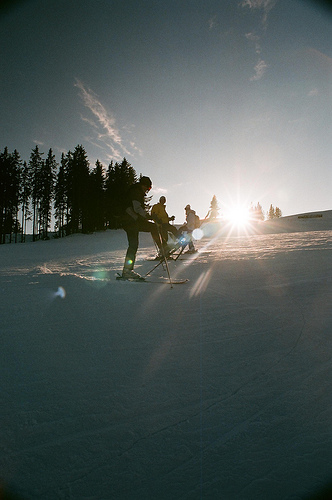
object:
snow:
[2, 211, 330, 499]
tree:
[104, 157, 140, 226]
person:
[176, 205, 197, 251]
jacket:
[186, 211, 197, 231]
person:
[150, 196, 180, 252]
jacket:
[151, 202, 169, 226]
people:
[118, 173, 170, 280]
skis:
[115, 273, 189, 283]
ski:
[144, 238, 193, 277]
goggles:
[141, 181, 153, 188]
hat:
[184, 205, 190, 210]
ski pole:
[156, 220, 173, 287]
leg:
[139, 220, 162, 249]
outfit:
[119, 184, 168, 270]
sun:
[215, 201, 260, 235]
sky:
[0, 1, 331, 234]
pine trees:
[0, 145, 17, 246]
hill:
[0, 210, 331, 498]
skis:
[167, 250, 198, 255]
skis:
[150, 239, 190, 259]